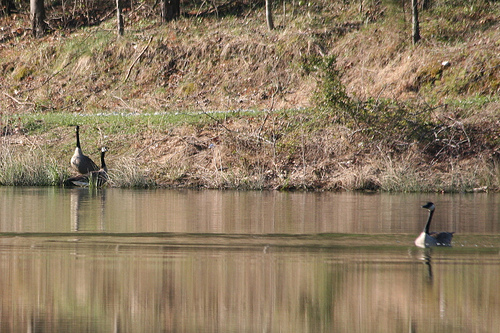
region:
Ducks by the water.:
[37, 99, 224, 228]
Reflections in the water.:
[63, 195, 286, 320]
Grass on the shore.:
[91, 88, 336, 192]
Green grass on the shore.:
[29, 101, 318, 189]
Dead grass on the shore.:
[109, 83, 362, 265]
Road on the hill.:
[93, 54, 265, 138]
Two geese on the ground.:
[43, 110, 191, 221]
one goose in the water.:
[388, 195, 498, 297]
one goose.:
[376, 184, 496, 288]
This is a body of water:
[22, 198, 382, 329]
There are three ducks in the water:
[57, 121, 477, 281]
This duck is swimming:
[398, 192, 460, 259]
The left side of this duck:
[412, 188, 462, 255]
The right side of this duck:
[55, 138, 136, 195]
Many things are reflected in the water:
[21, 258, 441, 332]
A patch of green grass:
[72, 105, 195, 131]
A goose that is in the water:
[406, 191, 456, 249]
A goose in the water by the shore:
[62, 141, 122, 188]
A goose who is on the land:
[57, 116, 94, 183]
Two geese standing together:
[57, 119, 121, 203]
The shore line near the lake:
[22, 102, 493, 199]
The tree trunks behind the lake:
[13, 6, 497, 84]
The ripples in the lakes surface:
[37, 221, 498, 268]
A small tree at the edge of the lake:
[306, 45, 491, 153]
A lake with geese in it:
[15, 112, 499, 332]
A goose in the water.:
[415, 200, 455, 248]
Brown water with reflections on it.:
[1, 184, 498, 332]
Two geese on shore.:
[71, 124, 111, 187]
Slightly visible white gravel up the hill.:
[57, 108, 286, 117]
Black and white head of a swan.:
[422, 201, 435, 212]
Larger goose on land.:
[71, 122, 100, 174]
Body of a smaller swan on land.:
[63, 168, 108, 190]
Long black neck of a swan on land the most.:
[73, 127, 81, 147]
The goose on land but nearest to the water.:
[63, 143, 113, 187]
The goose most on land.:
[68, 124, 100, 173]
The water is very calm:
[26, 201, 371, 331]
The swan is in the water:
[398, 183, 463, 253]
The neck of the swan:
[418, 213, 438, 235]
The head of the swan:
[418, 194, 444, 215]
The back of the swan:
[438, 224, 460, 246]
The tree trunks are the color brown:
[16, 1, 439, 46]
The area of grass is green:
[53, 100, 233, 134]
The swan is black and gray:
[413, 189, 465, 254]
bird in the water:
[351, 165, 473, 277]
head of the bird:
[401, 179, 458, 221]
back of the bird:
[429, 221, 463, 263]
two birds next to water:
[33, 107, 124, 212]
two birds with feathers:
[38, 93, 153, 214]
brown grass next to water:
[135, 108, 281, 192]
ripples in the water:
[140, 198, 285, 280]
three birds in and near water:
[10, 76, 491, 293]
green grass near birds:
[109, 100, 218, 139]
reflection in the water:
[223, 250, 350, 331]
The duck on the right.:
[410, 197, 453, 257]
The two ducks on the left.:
[66, 119, 111, 193]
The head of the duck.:
[422, 198, 434, 217]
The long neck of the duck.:
[73, 122, 84, 152]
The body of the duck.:
[63, 169, 110, 186]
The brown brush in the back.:
[145, 134, 267, 186]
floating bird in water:
[367, 174, 478, 274]